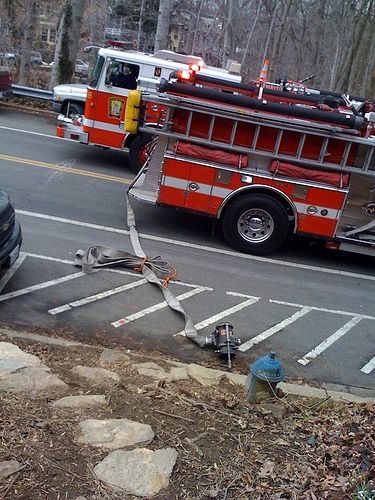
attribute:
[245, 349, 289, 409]
hydrant — blue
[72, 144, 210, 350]
hose — thick, gray, fire truck, fire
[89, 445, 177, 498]
rock — gray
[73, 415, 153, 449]
rock — gray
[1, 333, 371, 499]
dirt — brown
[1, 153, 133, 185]
line — yellow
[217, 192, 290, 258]
tire — black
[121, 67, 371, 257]
engine — red, white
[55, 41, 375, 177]
engine — red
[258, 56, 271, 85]
cone — orange, white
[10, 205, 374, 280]
line — white, painted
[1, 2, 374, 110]
trees — background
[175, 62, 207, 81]
lights — on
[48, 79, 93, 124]
truck — parked